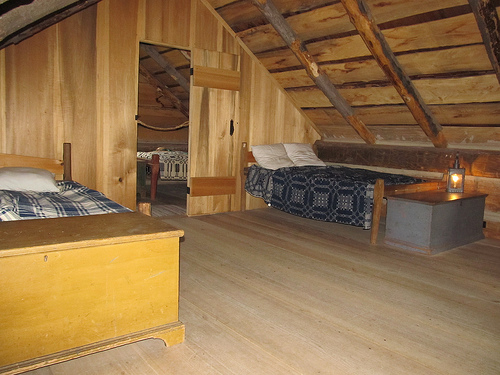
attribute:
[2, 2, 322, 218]
walls — wooden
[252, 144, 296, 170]
pillow — fluffy, white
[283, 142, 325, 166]
pillow — fluffy, white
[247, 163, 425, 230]
blanket — blue, gray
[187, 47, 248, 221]
door — wooden, open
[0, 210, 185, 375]
trunk — wooden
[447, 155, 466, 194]
lantern — small, square, gray, metal, lit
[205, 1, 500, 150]
ceiling — angled, wooden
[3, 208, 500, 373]
floor — wooden, brown, light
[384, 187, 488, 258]
trunk — wooden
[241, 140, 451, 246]
frame — wooden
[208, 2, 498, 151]
rafters — wooden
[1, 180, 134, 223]
blanket — plaid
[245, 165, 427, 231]
comforter — blue, gray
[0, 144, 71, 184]
frame — wooden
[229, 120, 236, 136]
handle — black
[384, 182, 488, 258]
chest — gray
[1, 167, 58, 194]
pillow — white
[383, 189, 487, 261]
box — wooden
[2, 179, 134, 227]
bedspread — blue, white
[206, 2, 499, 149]
roof — wooden, angled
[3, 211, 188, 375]
chest — brown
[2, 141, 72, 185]
head board — brown